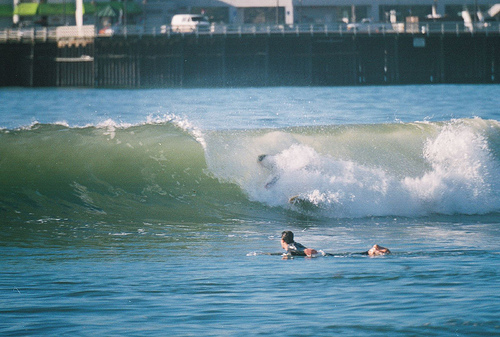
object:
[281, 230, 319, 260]
man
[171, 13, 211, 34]
van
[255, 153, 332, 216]
person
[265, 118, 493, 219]
wave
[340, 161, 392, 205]
ground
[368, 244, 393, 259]
feet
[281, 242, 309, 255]
wetsuit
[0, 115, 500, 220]
wave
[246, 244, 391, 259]
board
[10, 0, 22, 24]
umbrellas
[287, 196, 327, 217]
board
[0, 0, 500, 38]
city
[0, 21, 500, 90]
boardwalk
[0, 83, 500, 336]
water